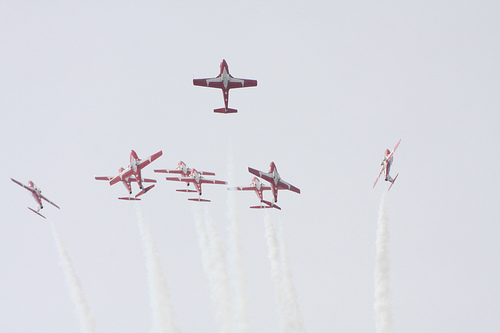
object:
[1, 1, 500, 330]
sky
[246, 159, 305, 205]
airplane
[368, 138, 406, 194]
plane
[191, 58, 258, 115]
plane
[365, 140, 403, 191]
planes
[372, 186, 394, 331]
smoke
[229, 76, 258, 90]
airplane wing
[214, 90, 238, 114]
tail section of plan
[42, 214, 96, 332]
smoke trails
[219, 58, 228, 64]
prop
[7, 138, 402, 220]
eight planes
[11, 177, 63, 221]
plane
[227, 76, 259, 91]
wings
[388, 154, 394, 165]
cockpit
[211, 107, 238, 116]
stabilizer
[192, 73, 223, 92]
side wing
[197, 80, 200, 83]
red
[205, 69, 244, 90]
white accents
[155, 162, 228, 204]
plane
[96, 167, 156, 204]
plane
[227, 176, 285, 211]
plane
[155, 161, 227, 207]
trick